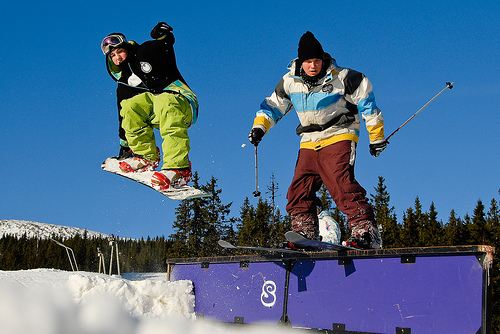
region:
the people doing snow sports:
[79, 16, 466, 266]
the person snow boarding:
[90, 18, 207, 201]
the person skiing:
[228, 27, 452, 263]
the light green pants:
[117, 84, 199, 181]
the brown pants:
[288, 138, 381, 230]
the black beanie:
[294, 27, 327, 60]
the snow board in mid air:
[96, 154, 209, 206]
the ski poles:
[249, 80, 461, 187]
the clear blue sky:
[390, 8, 494, 48]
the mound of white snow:
[25, 270, 172, 324]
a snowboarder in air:
[97, 22, 205, 207]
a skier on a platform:
[215, 26, 455, 253]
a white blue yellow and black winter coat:
[250, 66, 381, 143]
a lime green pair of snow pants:
[116, 82, 196, 167]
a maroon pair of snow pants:
[286, 146, 369, 227]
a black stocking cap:
[293, 31, 322, 63]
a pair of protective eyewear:
[100, 32, 123, 59]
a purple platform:
[164, 254, 484, 324]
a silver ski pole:
[250, 129, 262, 204]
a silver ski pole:
[378, 81, 458, 149]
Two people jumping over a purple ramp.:
[94, 16, 439, 253]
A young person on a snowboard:
[96, 17, 225, 222]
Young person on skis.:
[219, 42, 457, 256]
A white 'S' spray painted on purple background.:
[252, 269, 279, 314]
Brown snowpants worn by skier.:
[285, 135, 376, 248]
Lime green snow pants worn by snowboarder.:
[120, 89, 195, 165]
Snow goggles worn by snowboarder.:
[99, 33, 127, 54]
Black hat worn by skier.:
[292, 25, 329, 60]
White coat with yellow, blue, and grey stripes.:
[247, 66, 382, 147]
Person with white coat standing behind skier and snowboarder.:
[315, 197, 345, 243]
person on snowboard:
[75, 16, 225, 217]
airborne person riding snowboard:
[82, 18, 228, 218]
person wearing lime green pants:
[96, 18, 211, 210]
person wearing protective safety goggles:
[83, 19, 218, 216]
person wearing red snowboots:
[85, 15, 229, 217]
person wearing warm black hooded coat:
[88, 19, 223, 206]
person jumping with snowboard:
[88, 12, 230, 217]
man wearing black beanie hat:
[239, 15, 464, 265]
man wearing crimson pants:
[224, 16, 461, 261]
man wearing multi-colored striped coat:
[235, 19, 435, 264]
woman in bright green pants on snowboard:
[98, 20, 217, 200]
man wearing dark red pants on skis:
[251, 30, 388, 250]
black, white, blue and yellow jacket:
[249, 59, 387, 152]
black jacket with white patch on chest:
[107, 39, 186, 152]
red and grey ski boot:
[150, 167, 192, 188]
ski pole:
[373, 78, 455, 155]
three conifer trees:
[168, 170, 234, 259]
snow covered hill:
[0, 217, 135, 242]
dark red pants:
[287, 140, 376, 236]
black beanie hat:
[297, 30, 325, 61]